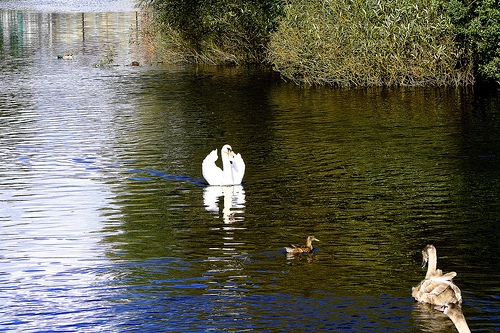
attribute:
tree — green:
[265, 4, 474, 87]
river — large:
[2, 1, 497, 331]